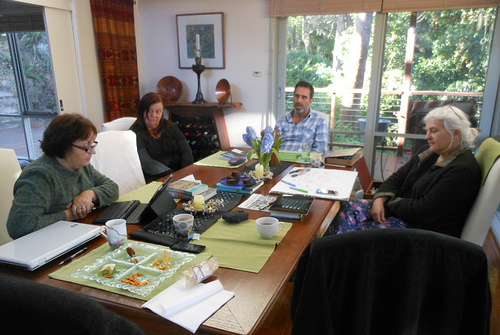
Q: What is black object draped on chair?
A: Jacket.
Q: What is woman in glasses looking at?
A: Tablet screen.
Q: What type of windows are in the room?
A: Sliding doors.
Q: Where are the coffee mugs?
A: On green placemats.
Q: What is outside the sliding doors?
A: Balcony.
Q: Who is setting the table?
A: Three women and a man.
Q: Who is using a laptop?
A: A woman with glasses on the left.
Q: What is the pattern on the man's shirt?
A: Plaid.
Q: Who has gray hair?
A: The woman on the right.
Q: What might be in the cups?
A: Coffee.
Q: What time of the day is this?
A: Morning.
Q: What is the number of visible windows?
A: Two.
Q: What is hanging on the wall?
A: A picture.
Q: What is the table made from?
A: Wood.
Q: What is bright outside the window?
A: The sun.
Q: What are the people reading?
A: Business reports.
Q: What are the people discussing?
A: Business.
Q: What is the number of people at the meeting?
A: Four.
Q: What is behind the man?
A: A deck.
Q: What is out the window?
A: Trees.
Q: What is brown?
A: Table.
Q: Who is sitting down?
A: Four people.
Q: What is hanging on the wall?
A: A painting.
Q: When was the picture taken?
A: Daytime.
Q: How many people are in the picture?
A: Four.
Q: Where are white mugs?
A: On the table.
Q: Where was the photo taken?
A: In a office building.